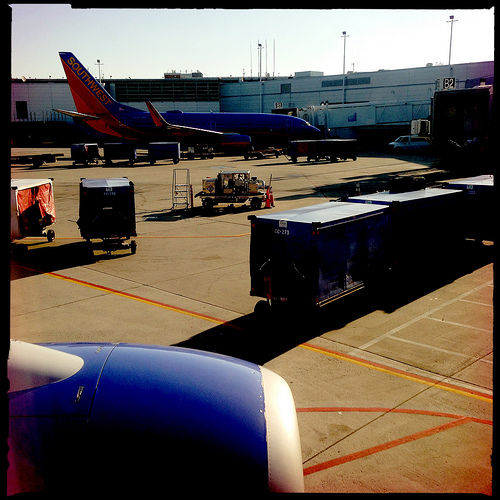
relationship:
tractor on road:
[198, 161, 267, 213] [118, 137, 331, 297]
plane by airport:
[39, 35, 326, 171] [219, 66, 481, 160]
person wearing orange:
[248, 176, 262, 195] [247, 183, 261, 194]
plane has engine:
[39, 35, 326, 171] [197, 121, 252, 149]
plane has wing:
[39, 35, 326, 171] [150, 100, 208, 156]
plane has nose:
[39, 35, 326, 171] [287, 112, 331, 153]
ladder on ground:
[167, 161, 197, 212] [23, 236, 254, 350]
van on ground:
[391, 125, 428, 158] [23, 236, 254, 350]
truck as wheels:
[81, 189, 136, 241] [96, 236, 136, 266]